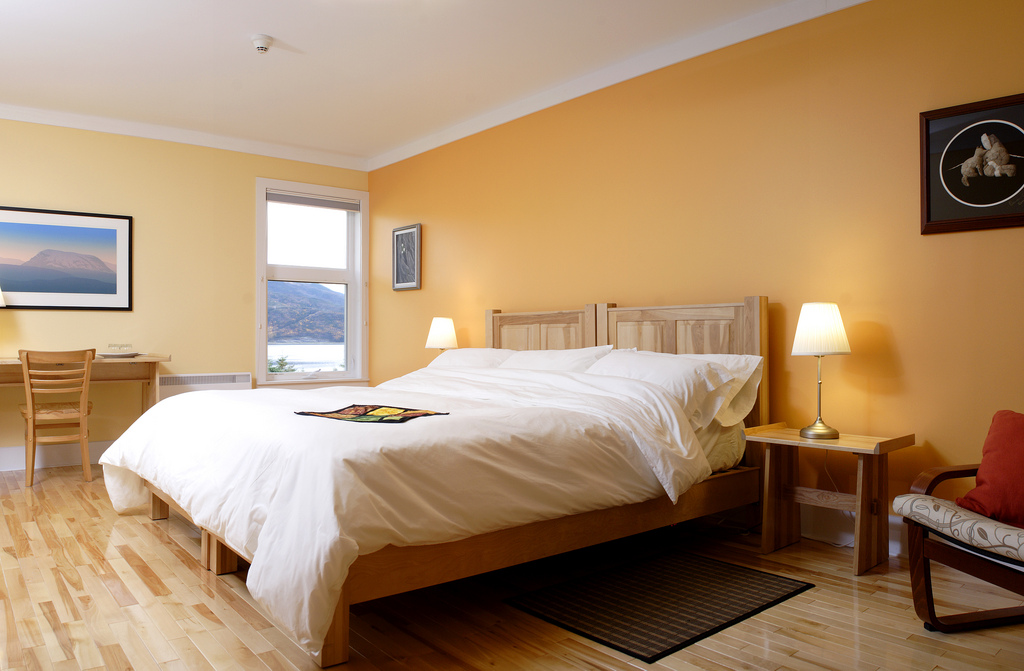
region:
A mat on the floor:
[507, 536, 825, 664]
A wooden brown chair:
[7, 329, 103, 491]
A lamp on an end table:
[731, 288, 924, 579]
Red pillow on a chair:
[880, 394, 1016, 642]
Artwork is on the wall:
[377, 209, 431, 295]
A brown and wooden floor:
[1, 450, 1016, 662]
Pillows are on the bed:
[412, 333, 767, 438]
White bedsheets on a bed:
[84, 337, 767, 661]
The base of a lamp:
[789, 409, 848, 449]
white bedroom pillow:
[577, 343, 758, 426]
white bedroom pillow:
[424, 347, 513, 371]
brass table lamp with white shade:
[792, 301, 851, 439]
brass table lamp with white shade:
[423, 314, 459, 347]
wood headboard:
[596, 295, 773, 431]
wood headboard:
[487, 303, 599, 346]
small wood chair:
[20, 346, 96, 480]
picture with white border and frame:
[392, 221, 422, 289]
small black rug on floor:
[566, 554, 836, 650]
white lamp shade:
[782, 270, 856, 404]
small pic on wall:
[376, 212, 441, 301]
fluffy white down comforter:
[160, 363, 581, 548]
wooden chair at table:
[0, 309, 122, 478]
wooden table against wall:
[16, 330, 182, 464]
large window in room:
[239, 170, 388, 395]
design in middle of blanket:
[310, 390, 451, 445]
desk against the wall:
[3, 345, 166, 451]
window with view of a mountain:
[235, 180, 378, 402]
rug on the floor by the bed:
[578, 540, 740, 667]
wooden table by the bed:
[741, 426, 901, 575]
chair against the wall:
[910, 398, 1021, 639]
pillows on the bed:
[428, 335, 729, 433]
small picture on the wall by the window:
[378, 215, 426, 296]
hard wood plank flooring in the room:
[21, 543, 174, 648]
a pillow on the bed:
[640, 306, 724, 461]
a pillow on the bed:
[462, 297, 532, 390]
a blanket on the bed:
[292, 326, 488, 510]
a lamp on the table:
[775, 265, 865, 443]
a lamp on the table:
[409, 309, 496, 417]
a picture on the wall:
[371, 177, 429, 279]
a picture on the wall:
[26, 171, 154, 314]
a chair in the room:
[851, 309, 1020, 616]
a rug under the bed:
[535, 481, 821, 668]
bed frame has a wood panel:
[687, 323, 704, 350]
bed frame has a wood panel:
[722, 322, 733, 352]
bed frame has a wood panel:
[675, 323, 692, 350]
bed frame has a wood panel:
[655, 322, 676, 355]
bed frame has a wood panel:
[640, 323, 657, 349]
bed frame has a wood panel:
[623, 322, 640, 341]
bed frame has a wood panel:
[570, 323, 583, 340]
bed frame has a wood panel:
[555, 322, 569, 346]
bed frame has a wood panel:
[541, 323, 554, 343]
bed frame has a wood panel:
[519, 326, 536, 343]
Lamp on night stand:
[762, 294, 876, 460]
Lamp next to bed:
[748, 288, 879, 456]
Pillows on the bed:
[439, 334, 743, 437]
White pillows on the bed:
[446, 337, 735, 430]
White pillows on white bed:
[441, 338, 758, 425]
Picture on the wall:
[3, 206, 152, 328]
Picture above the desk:
[0, 196, 162, 313]